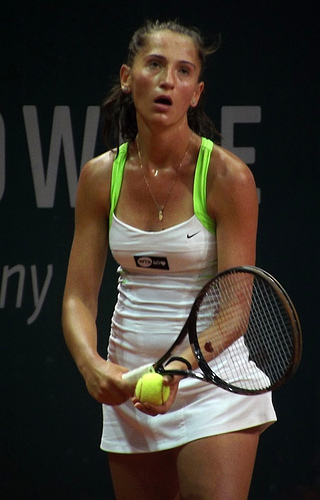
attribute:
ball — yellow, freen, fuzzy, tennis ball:
[132, 369, 181, 414]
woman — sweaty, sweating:
[69, 25, 283, 499]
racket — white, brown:
[86, 258, 308, 414]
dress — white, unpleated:
[93, 163, 251, 408]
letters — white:
[33, 101, 97, 162]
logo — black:
[132, 249, 173, 272]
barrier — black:
[237, 13, 307, 148]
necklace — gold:
[134, 149, 183, 224]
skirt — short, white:
[98, 330, 269, 442]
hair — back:
[114, 99, 136, 131]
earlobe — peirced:
[114, 70, 132, 100]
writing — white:
[19, 111, 90, 136]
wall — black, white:
[31, 12, 103, 79]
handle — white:
[120, 366, 158, 393]